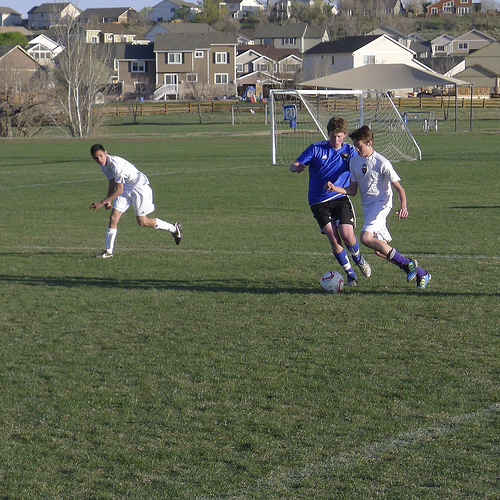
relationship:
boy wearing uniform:
[288, 117, 372, 288] [297, 139, 359, 206]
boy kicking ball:
[288, 117, 372, 288] [318, 269, 344, 291]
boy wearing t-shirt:
[279, 107, 387, 283] [293, 134, 358, 200]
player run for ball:
[325, 123, 432, 290] [308, 270, 349, 296]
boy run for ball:
[288, 117, 372, 288] [308, 270, 349, 296]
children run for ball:
[89, 143, 183, 260] [308, 270, 349, 296]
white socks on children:
[98, 217, 178, 255] [89, 143, 183, 260]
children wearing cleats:
[89, 143, 183, 260] [173, 221, 190, 242]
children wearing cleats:
[89, 143, 183, 260] [94, 253, 115, 266]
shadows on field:
[219, 250, 303, 327] [3, 146, 499, 500]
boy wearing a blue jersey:
[288, 117, 372, 288] [289, 141, 356, 208]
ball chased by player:
[319, 270, 344, 294] [325, 123, 434, 290]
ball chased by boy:
[319, 270, 344, 294] [288, 117, 372, 288]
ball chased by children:
[319, 270, 344, 294] [89, 143, 183, 260]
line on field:
[220, 393, 495, 500] [11, 258, 491, 482]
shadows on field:
[52, 279, 499, 298] [0, 115, 499, 500]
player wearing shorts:
[325, 123, 432, 290] [361, 205, 393, 240]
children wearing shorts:
[89, 143, 183, 260] [112, 184, 153, 216]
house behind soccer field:
[149, 31, 239, 103] [1, 111, 499, 498]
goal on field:
[236, 69, 431, 181] [3, 146, 499, 500]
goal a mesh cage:
[267, 88, 421, 168] [276, 83, 398, 149]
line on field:
[220, 393, 495, 500] [252, 173, 304, 197]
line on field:
[6, 237, 498, 259] [252, 173, 304, 197]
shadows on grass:
[3, 244, 499, 304] [16, 284, 491, 491]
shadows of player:
[3, 244, 499, 304] [325, 123, 432, 290]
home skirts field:
[148, 29, 239, 102] [0, 112, 497, 497]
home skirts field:
[302, 30, 414, 82] [0, 112, 497, 497]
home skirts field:
[2, 37, 39, 84] [0, 112, 497, 497]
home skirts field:
[446, 24, 498, 56] [0, 112, 497, 497]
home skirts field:
[248, 21, 330, 51] [0, 112, 497, 497]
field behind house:
[0, 115, 499, 500] [149, 24, 239, 103]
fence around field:
[402, 96, 483, 108] [0, 112, 497, 497]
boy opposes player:
[288, 117, 372, 288] [325, 123, 434, 290]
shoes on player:
[384, 250, 466, 310] [325, 123, 434, 290]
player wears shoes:
[325, 123, 434, 290] [384, 250, 466, 310]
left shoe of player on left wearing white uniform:
[100, 222, 130, 352] [101, 151, 154, 214]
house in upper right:
[427, 6, 474, 22] [298, 314, 423, 455]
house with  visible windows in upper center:
[149, 24, 239, 103] [260, 357, 470, 500]